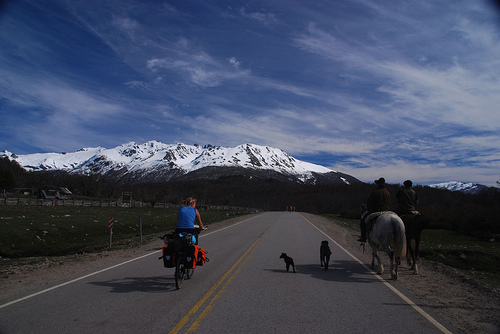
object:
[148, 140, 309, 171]
mountains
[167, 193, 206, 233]
woman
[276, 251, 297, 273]
dogs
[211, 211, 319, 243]
road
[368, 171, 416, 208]
people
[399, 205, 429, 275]
horses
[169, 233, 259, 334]
lines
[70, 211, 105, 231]
grass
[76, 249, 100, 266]
dirt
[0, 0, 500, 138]
sky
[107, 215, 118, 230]
sign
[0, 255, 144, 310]
lines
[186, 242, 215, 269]
tag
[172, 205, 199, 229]
shirt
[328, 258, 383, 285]
shadows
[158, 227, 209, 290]
bike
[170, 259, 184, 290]
wheel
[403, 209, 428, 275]
animal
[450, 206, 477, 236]
bushes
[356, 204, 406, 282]
horse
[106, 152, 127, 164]
snow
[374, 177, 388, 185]
hat